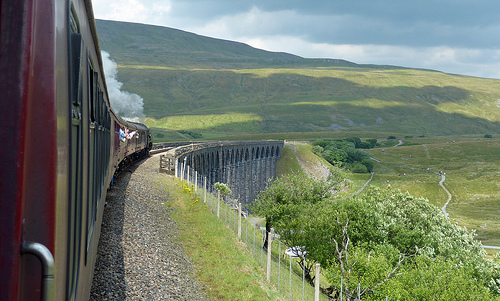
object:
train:
[0, 0, 153, 301]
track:
[1, 139, 225, 301]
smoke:
[98, 48, 144, 120]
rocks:
[158, 286, 162, 292]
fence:
[168, 139, 398, 300]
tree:
[360, 253, 499, 301]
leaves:
[211, 181, 233, 196]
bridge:
[173, 137, 285, 212]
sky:
[87, 0, 500, 81]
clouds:
[89, 0, 500, 81]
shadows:
[153, 104, 499, 139]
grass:
[345, 138, 499, 262]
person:
[120, 123, 127, 141]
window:
[85, 50, 90, 125]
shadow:
[84, 153, 145, 301]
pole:
[22, 237, 54, 300]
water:
[435, 169, 455, 236]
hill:
[97, 19, 499, 131]